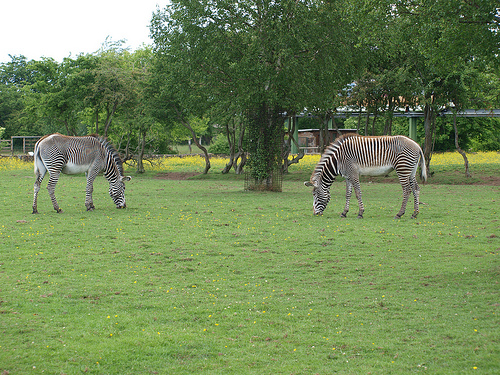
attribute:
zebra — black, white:
[308, 136, 429, 217]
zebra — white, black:
[268, 75, 498, 272]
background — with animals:
[1, 15, 498, 337]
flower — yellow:
[208, 277, 215, 282]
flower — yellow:
[195, 251, 199, 257]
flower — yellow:
[189, 254, 194, 257]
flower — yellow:
[200, 279, 205, 284]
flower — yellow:
[180, 285, 185, 290]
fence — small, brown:
[0, 134, 39, 157]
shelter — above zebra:
[296, 66, 458, 155]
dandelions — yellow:
[2, 148, 499, 171]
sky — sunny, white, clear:
[2, 0, 497, 100]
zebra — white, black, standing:
[30, 130, 131, 214]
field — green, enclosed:
[0, 224, 499, 374]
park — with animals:
[0, 2, 497, 372]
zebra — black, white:
[289, 119, 431, 220]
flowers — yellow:
[470, 365, 476, 372]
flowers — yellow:
[475, 324, 479, 336]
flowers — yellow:
[418, 362, 430, 370]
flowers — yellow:
[286, 342, 303, 352]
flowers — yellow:
[376, 287, 383, 299]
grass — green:
[62, 231, 439, 368]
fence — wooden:
[300, 123, 352, 143]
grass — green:
[20, 234, 495, 357]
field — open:
[149, 159, 244, 183]